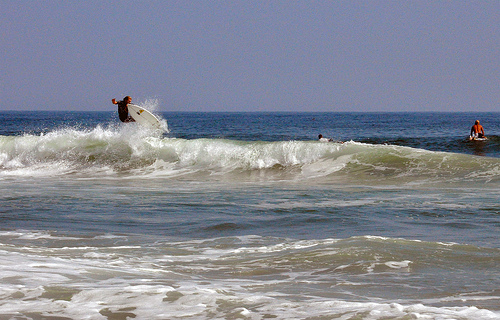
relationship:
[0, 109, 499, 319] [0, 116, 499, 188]
water with wave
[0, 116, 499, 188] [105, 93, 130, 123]
wave with person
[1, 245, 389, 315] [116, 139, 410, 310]
bubble forming on water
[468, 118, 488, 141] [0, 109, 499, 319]
man surfing in water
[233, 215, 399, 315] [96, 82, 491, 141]
waves of water with people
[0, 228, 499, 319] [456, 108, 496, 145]
waves of water with person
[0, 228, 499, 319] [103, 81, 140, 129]
waves of water with person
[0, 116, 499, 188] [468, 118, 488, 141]
wave of water with man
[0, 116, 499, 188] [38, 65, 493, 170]
wave of water with people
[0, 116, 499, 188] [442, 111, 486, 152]
wave of water with people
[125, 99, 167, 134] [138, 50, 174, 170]
surfboard in midair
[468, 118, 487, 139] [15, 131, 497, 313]
man riding his surfboard in ocean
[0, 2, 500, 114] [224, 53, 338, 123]
sky without clouds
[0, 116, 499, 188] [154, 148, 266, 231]
wave curling onto itself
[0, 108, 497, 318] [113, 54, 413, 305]
water in distance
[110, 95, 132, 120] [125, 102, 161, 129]
man riding a surfboard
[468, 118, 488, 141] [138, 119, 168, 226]
man sitting on h surfboard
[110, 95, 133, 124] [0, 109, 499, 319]
man surfing in water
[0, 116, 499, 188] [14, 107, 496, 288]
wave capped in ocean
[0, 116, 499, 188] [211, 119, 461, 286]
wave in ocean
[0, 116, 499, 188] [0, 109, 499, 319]
wave in water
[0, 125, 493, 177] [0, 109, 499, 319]
wave in water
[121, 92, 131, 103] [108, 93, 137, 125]
head on man